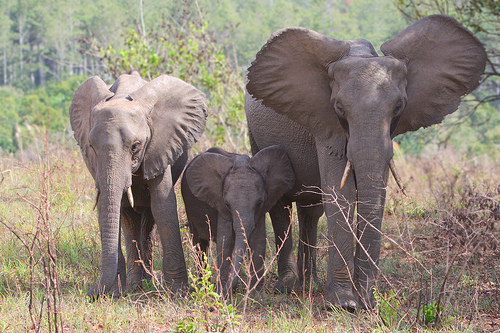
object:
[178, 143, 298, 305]
baby elephant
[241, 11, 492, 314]
elephant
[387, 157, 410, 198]
tusk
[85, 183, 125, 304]
trunk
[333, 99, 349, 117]
eyes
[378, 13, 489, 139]
big ears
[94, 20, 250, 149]
bushes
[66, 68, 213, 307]
elephants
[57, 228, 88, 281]
grass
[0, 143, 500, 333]
field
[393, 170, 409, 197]
mud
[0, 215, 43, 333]
sticks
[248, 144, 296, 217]
ear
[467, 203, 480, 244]
weeds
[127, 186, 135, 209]
small tusks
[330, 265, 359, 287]
wrinkles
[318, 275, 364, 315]
feet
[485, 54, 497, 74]
branch